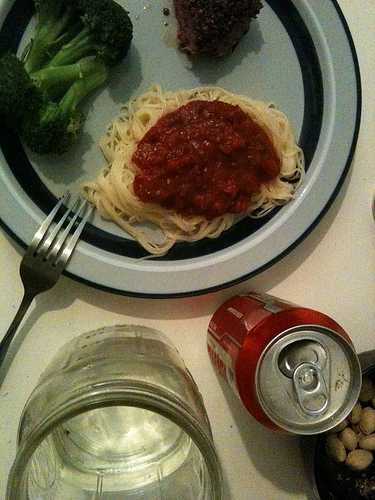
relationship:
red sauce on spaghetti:
[132, 98, 283, 216] [76, 79, 307, 259]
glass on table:
[40, 328, 228, 488] [39, 22, 370, 242]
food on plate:
[79, 83, 306, 264] [2, 0, 365, 300]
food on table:
[5, 7, 318, 261] [2, 2, 358, 498]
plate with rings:
[2, 0, 365, 300] [25, 161, 258, 263]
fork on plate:
[4, 188, 111, 295] [2, 0, 365, 300]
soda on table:
[214, 302, 365, 437] [318, 249, 365, 302]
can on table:
[205, 287, 363, 434] [319, 192, 364, 250]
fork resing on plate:
[0, 190, 94, 366] [2, 0, 365, 300]